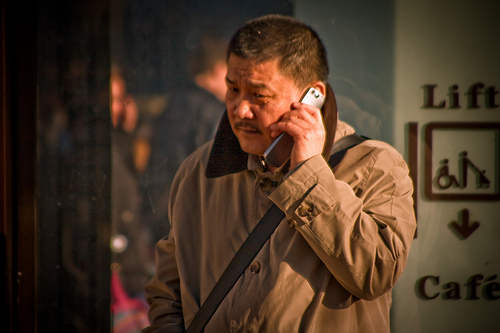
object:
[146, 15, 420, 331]
man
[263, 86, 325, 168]
phone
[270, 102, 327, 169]
hand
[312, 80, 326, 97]
ear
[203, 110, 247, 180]
collar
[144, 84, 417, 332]
coat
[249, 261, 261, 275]
button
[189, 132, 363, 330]
strap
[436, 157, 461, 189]
wheelchair logo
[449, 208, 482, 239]
arrow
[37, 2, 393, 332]
window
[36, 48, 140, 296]
people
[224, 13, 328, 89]
hair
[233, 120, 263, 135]
mustache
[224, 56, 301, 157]
face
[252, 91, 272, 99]
eyes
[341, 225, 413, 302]
elbow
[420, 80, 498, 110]
lift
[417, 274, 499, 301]
cafã©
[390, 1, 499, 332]
sign